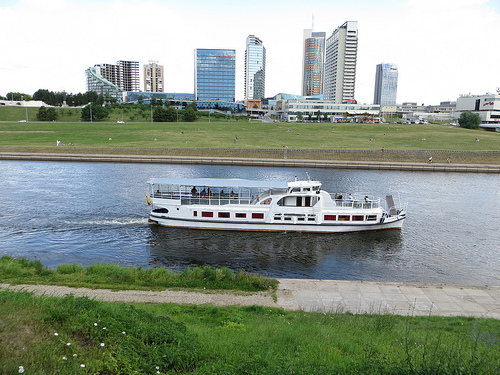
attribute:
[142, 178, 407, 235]
boat — moving, white, party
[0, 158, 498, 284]
river — dirty, canal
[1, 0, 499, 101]
sky — cloudy, bright, nice, clear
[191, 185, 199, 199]
person — numerous, enjoying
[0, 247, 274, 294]
grass — behind, numberous, weedy, lush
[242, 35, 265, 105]
buidling — big, tall, appealing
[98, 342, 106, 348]
flower — white